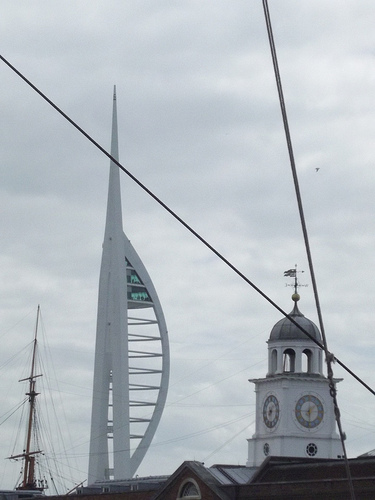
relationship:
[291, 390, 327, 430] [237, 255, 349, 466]
clock on tower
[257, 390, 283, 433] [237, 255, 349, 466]
clock on tower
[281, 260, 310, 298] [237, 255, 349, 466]
vane on tower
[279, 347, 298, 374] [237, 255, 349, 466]
arch on tower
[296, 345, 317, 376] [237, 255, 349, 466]
arch on tower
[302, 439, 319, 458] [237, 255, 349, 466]
circle on tower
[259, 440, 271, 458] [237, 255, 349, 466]
circle on tower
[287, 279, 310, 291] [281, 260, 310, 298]
arrow on vane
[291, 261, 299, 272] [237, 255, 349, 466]
point on tower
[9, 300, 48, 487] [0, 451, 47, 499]
mast of boat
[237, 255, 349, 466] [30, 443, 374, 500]
tower on building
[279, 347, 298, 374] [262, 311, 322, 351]
arch under dome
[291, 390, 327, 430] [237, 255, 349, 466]
clock in tower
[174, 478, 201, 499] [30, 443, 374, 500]
window on building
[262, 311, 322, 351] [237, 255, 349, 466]
dome of tower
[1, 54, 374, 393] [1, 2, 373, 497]
wires in sky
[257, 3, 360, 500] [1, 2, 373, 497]
wires in sky